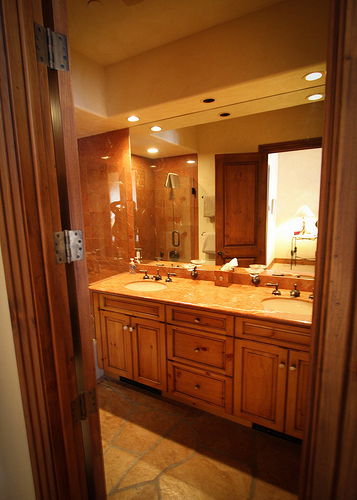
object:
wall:
[195, 100, 331, 286]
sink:
[125, 281, 165, 291]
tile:
[93, 377, 325, 499]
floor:
[57, 327, 356, 495]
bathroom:
[64, 2, 355, 494]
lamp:
[293, 204, 315, 238]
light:
[305, 69, 323, 82]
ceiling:
[107, 70, 329, 124]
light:
[128, 115, 141, 122]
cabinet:
[88, 271, 313, 444]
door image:
[216, 140, 323, 266]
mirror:
[128, 83, 333, 274]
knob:
[123, 325, 128, 331]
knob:
[128, 326, 133, 332]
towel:
[164, 173, 181, 189]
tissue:
[221, 257, 239, 271]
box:
[214, 268, 233, 287]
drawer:
[98, 289, 166, 324]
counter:
[87, 267, 313, 327]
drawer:
[98, 309, 131, 381]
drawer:
[131, 314, 167, 396]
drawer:
[164, 303, 233, 337]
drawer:
[233, 316, 323, 354]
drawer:
[233, 339, 289, 435]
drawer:
[165, 322, 235, 378]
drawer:
[167, 359, 236, 415]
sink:
[261, 290, 313, 315]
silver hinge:
[32, 23, 70, 74]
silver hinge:
[53, 230, 83, 265]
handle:
[172, 230, 181, 247]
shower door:
[154, 172, 194, 264]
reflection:
[110, 187, 137, 264]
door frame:
[298, 1, 355, 498]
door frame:
[1, 0, 109, 499]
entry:
[64, 0, 331, 499]